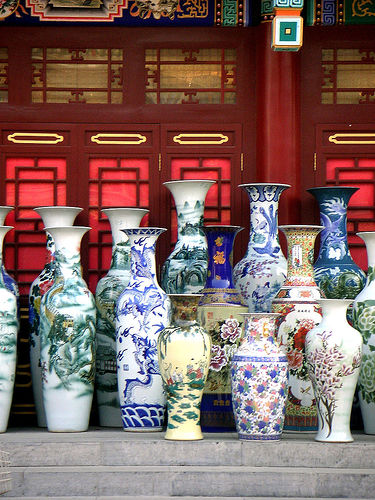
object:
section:
[89, 157, 150, 180]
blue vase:
[195, 223, 249, 433]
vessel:
[229, 312, 289, 443]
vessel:
[231, 182, 292, 312]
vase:
[229, 312, 290, 444]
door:
[0, 118, 245, 429]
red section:
[4, 155, 35, 179]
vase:
[156, 293, 212, 442]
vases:
[161, 180, 217, 294]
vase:
[114, 226, 171, 432]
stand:
[1, 434, 375, 499]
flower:
[292, 326, 311, 351]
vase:
[305, 186, 367, 327]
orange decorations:
[272, 7, 304, 49]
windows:
[4, 154, 232, 297]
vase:
[232, 182, 293, 313]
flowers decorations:
[305, 331, 362, 439]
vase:
[305, 299, 363, 444]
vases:
[38, 225, 96, 434]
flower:
[218, 317, 244, 346]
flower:
[206, 343, 229, 383]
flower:
[358, 351, 375, 405]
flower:
[352, 299, 374, 346]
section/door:
[2, 182, 68, 207]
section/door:
[86, 156, 150, 207]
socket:
[270, 15, 303, 52]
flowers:
[230, 363, 290, 442]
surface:
[2, 424, 374, 496]